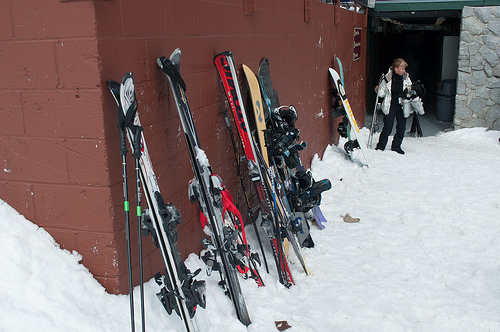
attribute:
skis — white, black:
[105, 68, 211, 330]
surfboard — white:
[325, 62, 375, 147]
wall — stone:
[451, 4, 499, 132]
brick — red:
[70, 13, 135, 61]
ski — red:
[209, 46, 300, 291]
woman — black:
[370, 55, 425, 155]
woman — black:
[373, 57, 432, 159]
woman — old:
[373, 57, 413, 154]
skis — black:
[154, 46, 262, 329]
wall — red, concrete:
[0, 0, 370, 293]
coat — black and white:
[365, 56, 428, 128]